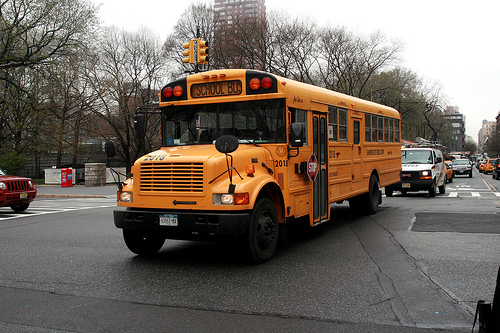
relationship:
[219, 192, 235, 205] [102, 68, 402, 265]
headlight mounted on schoolbus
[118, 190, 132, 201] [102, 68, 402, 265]
headlight mounted on schoolbus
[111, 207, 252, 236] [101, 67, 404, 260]
front bumper mounted on bus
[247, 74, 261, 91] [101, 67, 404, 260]
caution light mounted on bus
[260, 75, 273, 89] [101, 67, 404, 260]
caution light mounted on bus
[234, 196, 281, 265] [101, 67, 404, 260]
front tire mounted on bus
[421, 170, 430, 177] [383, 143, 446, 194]
headlight mounted on car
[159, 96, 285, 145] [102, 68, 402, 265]
windshield built into schoolbus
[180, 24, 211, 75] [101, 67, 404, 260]
street light standing behind bus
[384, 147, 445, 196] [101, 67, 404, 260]
car driving behind bus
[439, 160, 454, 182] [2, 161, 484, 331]
car driving on street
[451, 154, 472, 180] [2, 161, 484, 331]
car driving on street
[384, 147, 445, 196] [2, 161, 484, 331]
car driving on street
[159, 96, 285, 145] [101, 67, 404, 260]
windshield built into bus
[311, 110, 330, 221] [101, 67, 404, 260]
door leading to bus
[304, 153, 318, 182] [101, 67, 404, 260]
stop sign mounted on bus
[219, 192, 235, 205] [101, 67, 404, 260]
headlight mounted on bus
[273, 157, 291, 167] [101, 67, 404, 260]
number painted on bus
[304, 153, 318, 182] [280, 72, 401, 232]
stop sign on side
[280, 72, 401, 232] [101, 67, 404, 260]
side of bus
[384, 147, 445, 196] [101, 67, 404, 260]
car behind bus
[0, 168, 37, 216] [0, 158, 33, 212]
front end of car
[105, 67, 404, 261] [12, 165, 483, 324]
bus on road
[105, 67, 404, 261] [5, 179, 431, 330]
bus on road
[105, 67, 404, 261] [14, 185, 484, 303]
bus on road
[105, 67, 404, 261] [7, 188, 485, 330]
bus on road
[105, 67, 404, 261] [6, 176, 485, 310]
bus on road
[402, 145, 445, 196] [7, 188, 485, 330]
car travelling on road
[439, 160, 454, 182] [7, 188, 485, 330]
car travelling on road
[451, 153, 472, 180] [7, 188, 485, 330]
car travelling on road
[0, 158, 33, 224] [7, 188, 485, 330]
car travelling on road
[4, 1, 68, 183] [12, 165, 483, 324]
tree lines road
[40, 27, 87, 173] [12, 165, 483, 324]
tree lines road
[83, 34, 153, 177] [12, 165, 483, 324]
tree lines road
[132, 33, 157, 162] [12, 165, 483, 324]
tree lines road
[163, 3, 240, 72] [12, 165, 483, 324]
tree lines road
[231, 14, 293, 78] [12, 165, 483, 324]
tree lines road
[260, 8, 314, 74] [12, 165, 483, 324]
tree lines road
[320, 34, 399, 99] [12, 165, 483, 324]
tree lines road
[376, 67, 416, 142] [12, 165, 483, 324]
tree lines road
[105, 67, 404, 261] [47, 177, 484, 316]
bus driving through intersection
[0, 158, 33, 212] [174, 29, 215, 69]
car waiting at stop light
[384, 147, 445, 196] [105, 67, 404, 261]
car following bus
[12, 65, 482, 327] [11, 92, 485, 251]
street with cars